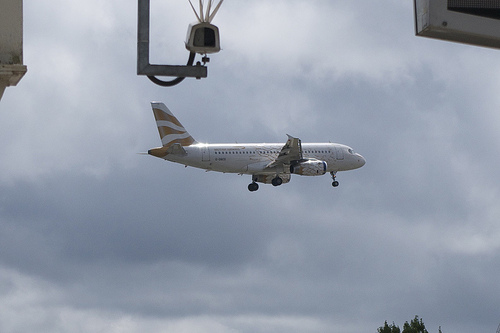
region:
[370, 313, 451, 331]
Leaf covered tree tops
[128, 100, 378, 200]
Airplane preparing to land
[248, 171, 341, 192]
Landing gear of airplane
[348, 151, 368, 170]
Side view of nose of airplane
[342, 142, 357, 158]
Cockpit of airplane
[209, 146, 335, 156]
Passenger windows on airplane fuselage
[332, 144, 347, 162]
Closed airplane egress door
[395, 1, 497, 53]
Corner of metal sign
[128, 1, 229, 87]
Electronic equipment on metal bracket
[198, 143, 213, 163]
Rear egress door on airplane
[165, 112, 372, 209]
Airplane flying insky.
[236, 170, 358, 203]
Landing gear is down.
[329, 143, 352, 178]
White door on side of plane.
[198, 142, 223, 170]
White door on side of plane.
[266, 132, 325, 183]
Large wing on side of plane.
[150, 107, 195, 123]
Gold marking on tail of plane.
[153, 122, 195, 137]
Gold marking on tail of plane.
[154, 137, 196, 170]
Gold marking on tail of plane.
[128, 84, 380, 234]
Plane is mostly white in color.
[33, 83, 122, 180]
White couds in sky.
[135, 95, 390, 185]
this is a plane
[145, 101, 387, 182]
the plane is on air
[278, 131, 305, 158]
this is a wing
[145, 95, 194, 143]
this is the tail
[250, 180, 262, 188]
these are the wheels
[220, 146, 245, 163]
the plane is white in color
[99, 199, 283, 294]
this is the sky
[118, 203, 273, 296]
the sky is grey in color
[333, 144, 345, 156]
the door is closed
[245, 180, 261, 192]
the wheels are black in color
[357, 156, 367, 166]
The nose of the plane.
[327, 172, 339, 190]
The front wheel of the plane.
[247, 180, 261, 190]
The left wheels of the plane.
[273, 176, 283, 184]
The right wheels of the plane.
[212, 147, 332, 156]
The passenger windows on the plane.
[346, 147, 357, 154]
The windows in the cockpit area.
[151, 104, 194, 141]
The tail of the plane.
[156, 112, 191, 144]
The design on the tail of the plane.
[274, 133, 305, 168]
The large side wing of the plane.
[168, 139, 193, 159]
The small wing near the tail of the plane.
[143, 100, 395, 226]
WHITE AIRLINER IN SKY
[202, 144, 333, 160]
ROW OF WINDOWS FOR PASSENGERS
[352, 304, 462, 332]
GREEN LEAVES ON TREE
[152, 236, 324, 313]
WHITE CLOUDS IN SKY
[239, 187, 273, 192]
LOWERED LANDING GEAR OF PLANE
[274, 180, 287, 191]
LOWERED LANDING GEAR OF PLANE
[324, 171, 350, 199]
LOWERED LANDING GEAR OF PLANE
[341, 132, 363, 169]
COCKPIT WINDOWS ON PLANE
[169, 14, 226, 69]
SMALL CAMERA ABOVE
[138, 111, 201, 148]
YELLOW LINES ON PLANE